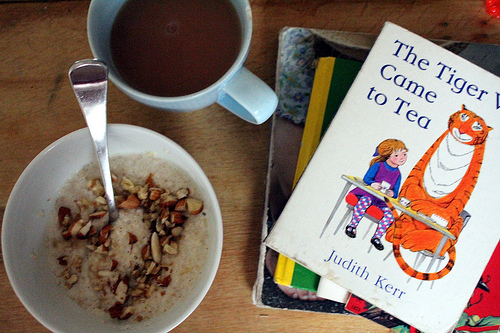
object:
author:
[322, 249, 408, 298]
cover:
[264, 21, 499, 330]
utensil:
[67, 58, 130, 211]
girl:
[343, 138, 407, 250]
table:
[2, 2, 500, 333]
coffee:
[110, 0, 242, 97]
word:
[323, 248, 407, 302]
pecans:
[164, 244, 178, 255]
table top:
[1, 2, 500, 333]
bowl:
[0, 122, 225, 332]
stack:
[247, 22, 499, 329]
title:
[363, 37, 500, 132]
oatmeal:
[181, 229, 209, 268]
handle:
[218, 71, 281, 125]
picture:
[317, 103, 493, 292]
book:
[261, 22, 498, 333]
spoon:
[67, 58, 119, 218]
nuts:
[187, 199, 205, 215]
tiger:
[387, 103, 494, 280]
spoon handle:
[68, 58, 108, 138]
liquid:
[105, 2, 241, 99]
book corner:
[271, 23, 336, 61]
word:
[378, 60, 438, 102]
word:
[364, 86, 433, 131]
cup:
[79, 0, 277, 124]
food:
[38, 156, 207, 319]